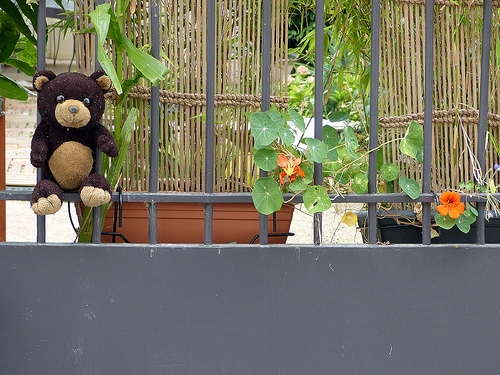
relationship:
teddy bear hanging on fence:
[29, 69, 121, 218] [0, 0, 499, 243]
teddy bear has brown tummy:
[29, 69, 121, 218] [47, 140, 95, 188]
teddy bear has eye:
[29, 69, 121, 218] [57, 95, 67, 105]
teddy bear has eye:
[29, 69, 121, 218] [82, 96, 90, 106]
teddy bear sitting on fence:
[29, 69, 121, 218] [0, 0, 499, 243]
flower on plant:
[439, 191, 465, 220] [248, 107, 482, 231]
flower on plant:
[277, 154, 305, 183] [248, 107, 482, 231]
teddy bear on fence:
[29, 69, 121, 218] [0, 0, 499, 243]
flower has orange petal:
[439, 191, 465, 220] [439, 191, 452, 203]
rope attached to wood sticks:
[114, 78, 290, 108] [73, 0, 293, 192]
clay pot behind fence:
[76, 198, 295, 243] [0, 0, 499, 243]